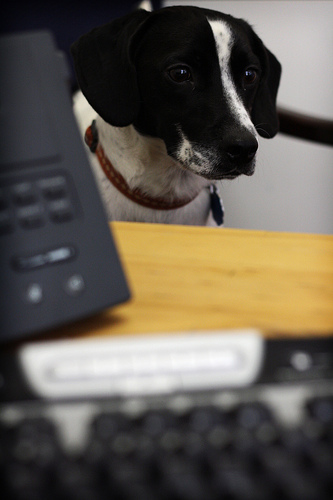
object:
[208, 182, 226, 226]
name tag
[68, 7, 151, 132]
dog ear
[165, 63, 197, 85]
dog eye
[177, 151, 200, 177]
whiskers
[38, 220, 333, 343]
desk top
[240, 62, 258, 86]
eyes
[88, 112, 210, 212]
neck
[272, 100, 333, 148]
moulding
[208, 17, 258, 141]
stripe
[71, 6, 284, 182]
head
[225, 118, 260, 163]
dog nose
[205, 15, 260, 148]
stripe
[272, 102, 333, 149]
baseboard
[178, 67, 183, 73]
reflection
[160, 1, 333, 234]
wall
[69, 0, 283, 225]
dog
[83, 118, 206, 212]
collar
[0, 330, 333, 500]
keyboard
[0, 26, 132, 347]
phone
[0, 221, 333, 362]
desk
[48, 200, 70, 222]
button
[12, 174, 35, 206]
button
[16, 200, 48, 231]
button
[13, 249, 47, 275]
button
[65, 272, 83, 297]
button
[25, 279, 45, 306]
button